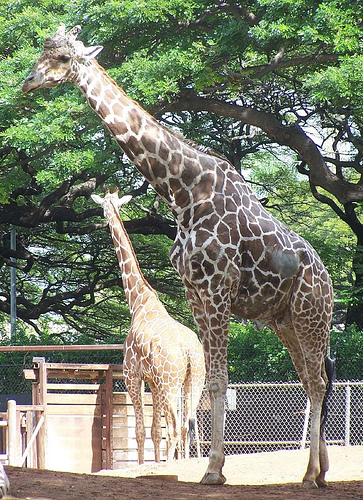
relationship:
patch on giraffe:
[244, 231, 300, 310] [20, 21, 336, 492]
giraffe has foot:
[87, 185, 205, 465] [202, 452, 227, 486]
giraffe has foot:
[87, 185, 205, 465] [301, 459, 320, 490]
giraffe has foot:
[87, 185, 205, 465] [315, 460, 329, 489]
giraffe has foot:
[87, 185, 205, 465] [198, 454, 226, 485]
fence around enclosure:
[1, 362, 361, 457] [5, 333, 360, 497]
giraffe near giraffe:
[20, 21, 336, 492] [87, 185, 205, 465]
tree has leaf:
[254, 158, 361, 284] [333, 50, 352, 65]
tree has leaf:
[226, 324, 298, 382] [239, 325, 252, 336]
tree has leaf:
[1, 0, 233, 207] [82, 147, 97, 160]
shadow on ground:
[10, 456, 361, 499] [0, 445, 359, 498]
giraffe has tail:
[89, 189, 206, 464] [178, 364, 194, 431]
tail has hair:
[178, 364, 194, 431] [179, 425, 191, 448]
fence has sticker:
[183, 379, 361, 459] [198, 388, 236, 410]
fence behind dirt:
[230, 364, 299, 454] [221, 439, 303, 486]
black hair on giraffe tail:
[320, 355, 337, 441] [320, 322, 332, 443]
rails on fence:
[340, 370, 355, 475] [1, 362, 361, 457]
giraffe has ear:
[18, 9, 345, 422] [81, 43, 107, 58]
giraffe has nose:
[20, 21, 336, 492] [21, 74, 38, 90]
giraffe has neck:
[20, 21, 336, 492] [79, 72, 213, 205]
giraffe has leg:
[20, 21, 336, 492] [200, 308, 225, 488]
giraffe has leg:
[20, 21, 336, 492] [191, 308, 210, 360]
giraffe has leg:
[20, 21, 336, 492] [275, 321, 308, 376]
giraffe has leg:
[20, 21, 336, 492] [294, 323, 340, 438]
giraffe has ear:
[20, 21, 336, 492] [83, 41, 103, 58]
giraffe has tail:
[20, 21, 336, 492] [321, 295, 337, 431]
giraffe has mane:
[20, 21, 336, 492] [73, 37, 227, 159]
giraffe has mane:
[87, 185, 205, 465] [109, 200, 163, 303]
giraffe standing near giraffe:
[87, 185, 205, 465] [20, 21, 336, 492]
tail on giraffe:
[189, 357, 195, 441] [89, 189, 206, 464]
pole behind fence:
[7, 223, 18, 345] [1, 362, 361, 457]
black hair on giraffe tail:
[320, 355, 337, 441] [319, 322, 336, 443]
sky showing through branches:
[305, 123, 322, 136] [242, 57, 316, 97]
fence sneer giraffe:
[12, 350, 198, 476] [20, 21, 336, 492]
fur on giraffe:
[214, 296, 216, 306] [20, 21, 336, 492]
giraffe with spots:
[20, 21, 336, 492] [189, 271, 229, 356]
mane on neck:
[108, 197, 159, 293] [107, 212, 151, 307]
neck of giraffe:
[107, 212, 151, 307] [85, 187, 214, 473]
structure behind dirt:
[10, 350, 192, 463] [2, 439, 360, 498]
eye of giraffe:
[57, 53, 71, 62] [20, 21, 336, 492]